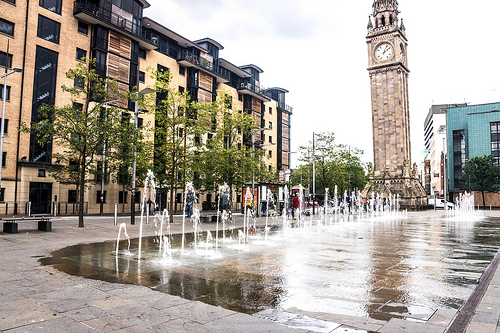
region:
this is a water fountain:
[105, 140, 473, 328]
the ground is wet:
[42, 231, 108, 307]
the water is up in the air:
[105, 150, 473, 277]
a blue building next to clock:
[422, 94, 491, 205]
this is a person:
[283, 182, 303, 219]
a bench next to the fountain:
[6, 207, 51, 240]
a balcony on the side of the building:
[175, 42, 242, 81]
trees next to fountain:
[48, 56, 377, 216]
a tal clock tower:
[364, 2, 428, 208]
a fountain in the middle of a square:
[110, 182, 478, 283]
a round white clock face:
[372, 38, 395, 62]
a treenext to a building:
[456, 152, 499, 209]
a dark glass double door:
[29, 179, 55, 216]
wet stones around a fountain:
[41, 212, 497, 320]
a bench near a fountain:
[0, 207, 60, 237]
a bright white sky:
[145, 0, 499, 179]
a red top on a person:
[290, 193, 301, 209]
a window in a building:
[0, 16, 16, 35]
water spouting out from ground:
[116, 226, 133, 257]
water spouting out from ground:
[136, 190, 148, 262]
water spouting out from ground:
[156, 212, 179, 261]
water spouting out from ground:
[177, 178, 198, 253]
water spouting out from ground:
[211, 198, 235, 248]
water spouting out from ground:
[235, 180, 260, 241]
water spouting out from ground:
[258, 191, 280, 248]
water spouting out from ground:
[278, 186, 289, 238]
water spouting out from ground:
[292, 177, 304, 224]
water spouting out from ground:
[310, 187, 331, 227]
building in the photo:
[2, 26, 286, 213]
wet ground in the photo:
[275, 235, 372, 286]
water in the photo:
[91, 177, 371, 279]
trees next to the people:
[28, 101, 255, 211]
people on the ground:
[271, 179, 317, 220]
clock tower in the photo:
[342, 13, 429, 114]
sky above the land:
[277, 18, 354, 83]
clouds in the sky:
[246, 10, 344, 57]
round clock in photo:
[357, 35, 404, 74]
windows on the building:
[117, 57, 205, 112]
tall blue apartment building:
[443, 103, 499, 208]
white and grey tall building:
[420, 103, 470, 206]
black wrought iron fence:
[3, 199, 88, 214]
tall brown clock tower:
[362, 0, 426, 213]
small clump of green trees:
[294, 133, 373, 198]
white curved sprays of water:
[113, 169, 409, 270]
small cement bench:
[1, 214, 54, 232]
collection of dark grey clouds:
[175, 2, 322, 48]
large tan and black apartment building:
[5, 0, 298, 222]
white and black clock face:
[374, 41, 395, 63]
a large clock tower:
[355, 0, 440, 211]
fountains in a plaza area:
[99, 164, 491, 259]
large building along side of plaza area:
[3, 5, 330, 230]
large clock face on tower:
[369, 38, 399, 63]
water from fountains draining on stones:
[206, 248, 485, 330]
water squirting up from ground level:
[111, 215, 168, 269]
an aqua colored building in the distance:
[438, 97, 499, 209]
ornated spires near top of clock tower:
[354, 8, 423, 36]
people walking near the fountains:
[285, 184, 308, 222]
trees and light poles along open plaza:
[65, 109, 385, 223]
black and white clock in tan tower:
[362, 3, 408, 151]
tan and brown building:
[23, 8, 308, 180]